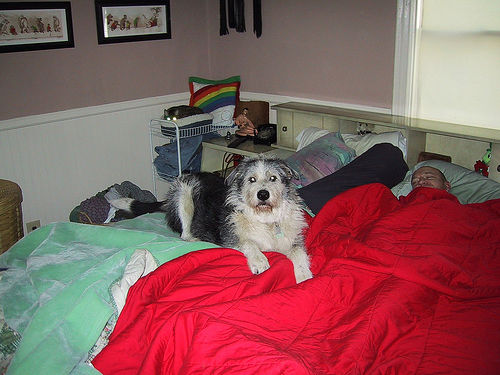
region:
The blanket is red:
[266, 323, 330, 370]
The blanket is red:
[354, 305, 416, 367]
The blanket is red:
[277, 345, 322, 368]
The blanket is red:
[331, 321, 379, 364]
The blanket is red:
[280, 269, 335, 344]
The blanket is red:
[307, 273, 370, 368]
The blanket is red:
[294, 302, 339, 362]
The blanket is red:
[301, 262, 352, 345]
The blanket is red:
[340, 341, 368, 368]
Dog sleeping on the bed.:
[112, 155, 340, 285]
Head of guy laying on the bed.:
[409, 162, 447, 197]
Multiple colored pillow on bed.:
[277, 133, 354, 188]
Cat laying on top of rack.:
[157, 104, 214, 121]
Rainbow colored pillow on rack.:
[186, 70, 239, 123]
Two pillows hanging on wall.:
[2, 2, 174, 54]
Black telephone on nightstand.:
[247, 120, 279, 145]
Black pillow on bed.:
[295, 140, 407, 213]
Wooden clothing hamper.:
[0, 175, 24, 250]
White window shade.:
[415, 1, 499, 116]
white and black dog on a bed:
[161, 154, 336, 284]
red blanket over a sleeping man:
[94, 155, 499, 369]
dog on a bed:
[159, 155, 332, 280]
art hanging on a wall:
[92, 1, 176, 45]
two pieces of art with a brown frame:
[3, 1, 190, 63]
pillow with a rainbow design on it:
[185, 74, 238, 127]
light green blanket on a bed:
[2, 218, 224, 374]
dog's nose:
[260, 187, 272, 197]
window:
[408, 1, 499, 136]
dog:
[161, 154, 322, 284]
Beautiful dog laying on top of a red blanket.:
[173, 157, 316, 288]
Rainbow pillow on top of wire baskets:
[181, 66, 246, 129]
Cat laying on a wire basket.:
[156, 103, 227, 133]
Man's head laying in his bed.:
[402, 153, 472, 220]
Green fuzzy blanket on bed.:
[3, 235, 107, 371]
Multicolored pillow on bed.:
[293, 136, 363, 179]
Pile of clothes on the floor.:
[64, 186, 164, 224]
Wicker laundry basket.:
[0, 182, 42, 265]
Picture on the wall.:
[85, 6, 197, 46]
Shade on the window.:
[400, 17, 499, 123]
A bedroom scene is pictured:
[17, 27, 488, 362]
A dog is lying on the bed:
[94, 151, 356, 299]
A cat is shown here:
[156, 101, 219, 138]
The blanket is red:
[331, 215, 468, 367]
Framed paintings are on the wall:
[1, 2, 181, 48]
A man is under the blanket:
[394, 157, 459, 262]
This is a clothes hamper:
[0, 167, 25, 253]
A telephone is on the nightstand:
[251, 119, 280, 149]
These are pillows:
[297, 126, 404, 191]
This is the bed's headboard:
[267, 94, 497, 165]